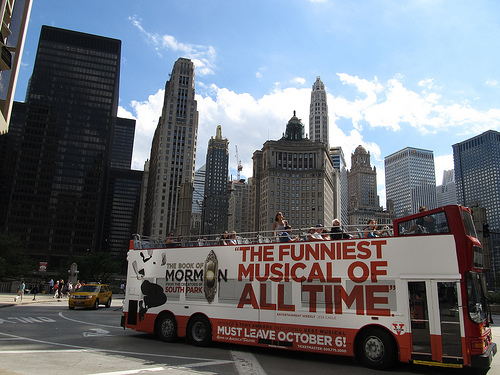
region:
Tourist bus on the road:
[126, 191, 487, 362]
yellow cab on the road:
[56, 271, 121, 322]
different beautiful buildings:
[38, 28, 484, 208]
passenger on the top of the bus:
[142, 197, 452, 255]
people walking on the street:
[2, 267, 72, 312]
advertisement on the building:
[126, 245, 481, 350]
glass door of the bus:
[392, 267, 462, 372]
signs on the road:
[2, 305, 279, 368]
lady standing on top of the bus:
[261, 205, 292, 256]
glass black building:
[33, 25, 125, 272]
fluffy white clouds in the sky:
[221, 99, 288, 122]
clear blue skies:
[171, 17, 265, 29]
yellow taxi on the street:
[60, 278, 122, 319]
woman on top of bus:
[268, 206, 298, 246]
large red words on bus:
[231, 244, 396, 310]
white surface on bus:
[393, 240, 438, 264]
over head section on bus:
[132, 209, 482, 249]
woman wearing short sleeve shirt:
[263, 203, 303, 240]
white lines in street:
[28, 307, 143, 357]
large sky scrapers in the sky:
[109, 35, 471, 205]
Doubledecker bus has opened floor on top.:
[109, 183, 495, 372]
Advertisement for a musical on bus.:
[224, 237, 405, 337]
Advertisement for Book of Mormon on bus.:
[152, 247, 235, 317]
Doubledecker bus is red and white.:
[110, 197, 499, 373]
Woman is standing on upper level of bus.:
[266, 202, 297, 249]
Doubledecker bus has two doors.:
[396, 270, 473, 367]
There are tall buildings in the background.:
[0, 8, 499, 311]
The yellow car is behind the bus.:
[61, 274, 119, 324]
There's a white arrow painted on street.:
[66, 322, 131, 348]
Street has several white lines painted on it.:
[1, 300, 268, 374]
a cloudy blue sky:
[0, 0, 499, 210]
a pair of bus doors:
[400, 275, 467, 369]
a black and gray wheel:
[353, 325, 395, 368]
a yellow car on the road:
[66, 280, 112, 316]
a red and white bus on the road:
[118, 196, 498, 373]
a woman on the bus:
[268, 208, 290, 241]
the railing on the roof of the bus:
[128, 220, 394, 252]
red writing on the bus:
[231, 236, 398, 322]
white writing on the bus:
[214, 323, 349, 354]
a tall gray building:
[136, 54, 203, 244]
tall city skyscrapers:
[15, 68, 484, 273]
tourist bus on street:
[113, 189, 479, 353]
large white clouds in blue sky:
[224, 71, 301, 142]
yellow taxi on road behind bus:
[60, 265, 125, 312]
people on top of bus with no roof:
[139, 178, 449, 256]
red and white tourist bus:
[104, 231, 499, 352]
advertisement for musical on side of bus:
[128, 215, 394, 321]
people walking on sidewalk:
[18, 265, 102, 303]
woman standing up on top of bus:
[264, 200, 305, 247]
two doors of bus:
[392, 268, 486, 370]